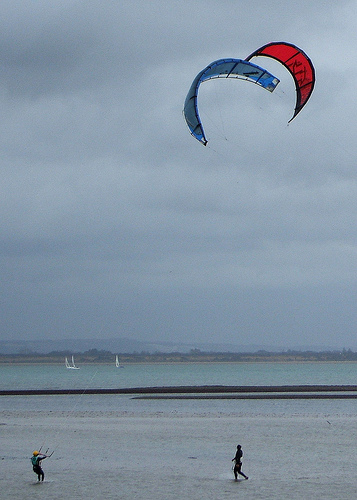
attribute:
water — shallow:
[3, 366, 356, 493]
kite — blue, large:
[184, 56, 280, 145]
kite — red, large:
[242, 39, 314, 123]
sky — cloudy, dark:
[2, 1, 355, 354]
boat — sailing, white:
[109, 353, 125, 374]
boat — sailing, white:
[64, 352, 80, 370]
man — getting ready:
[27, 449, 54, 481]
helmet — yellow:
[32, 448, 41, 458]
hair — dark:
[234, 443, 243, 451]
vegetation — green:
[53, 349, 112, 357]